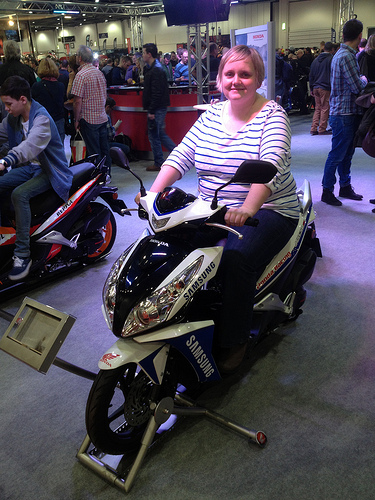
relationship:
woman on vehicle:
[133, 44, 301, 371] [83, 146, 323, 457]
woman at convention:
[133, 44, 301, 371] [1, 2, 374, 500]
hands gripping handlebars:
[133, 191, 249, 230] [217, 207, 259, 227]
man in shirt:
[318, 18, 369, 207] [329, 44, 367, 117]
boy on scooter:
[0, 73, 75, 282] [2, 152, 118, 303]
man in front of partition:
[141, 42, 178, 172] [108, 81, 220, 160]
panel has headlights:
[102, 229, 225, 339] [102, 241, 204, 338]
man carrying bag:
[69, 44, 111, 183] [68, 129, 88, 165]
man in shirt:
[69, 44, 111, 183] [69, 61, 111, 124]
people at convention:
[2, 18, 375, 373] [1, 2, 374, 500]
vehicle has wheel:
[83, 146, 323, 457] [85, 354, 178, 457]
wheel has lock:
[85, 354, 178, 457] [75, 395, 207, 494]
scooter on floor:
[2, 152, 118, 303] [0, 112, 373, 498]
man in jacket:
[141, 42, 178, 172] [143, 59, 170, 110]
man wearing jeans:
[141, 42, 178, 172] [145, 109, 174, 167]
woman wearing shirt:
[133, 44, 301, 371] [160, 97, 301, 220]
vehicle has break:
[83, 146, 323, 457] [119, 206, 243, 240]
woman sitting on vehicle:
[133, 44, 301, 371] [83, 146, 323, 457]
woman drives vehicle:
[133, 44, 301, 371] [83, 146, 323, 457]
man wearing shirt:
[318, 18, 369, 207] [329, 44, 367, 117]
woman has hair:
[133, 44, 301, 371] [215, 45, 266, 96]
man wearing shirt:
[69, 44, 111, 183] [69, 61, 111, 124]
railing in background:
[15, 1, 212, 109] [2, 0, 373, 172]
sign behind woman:
[229, 22, 274, 105] [133, 44, 301, 371]